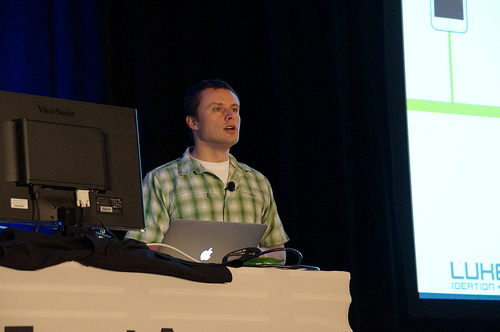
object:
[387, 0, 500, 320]
computer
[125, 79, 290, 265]
guy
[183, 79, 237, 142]
hair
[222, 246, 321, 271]
cables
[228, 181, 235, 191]
microphone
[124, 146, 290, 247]
shirt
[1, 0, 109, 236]
drapes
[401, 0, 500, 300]
display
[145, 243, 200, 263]
cords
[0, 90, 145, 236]
computer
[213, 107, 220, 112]
eye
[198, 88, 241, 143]
face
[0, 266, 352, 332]
desk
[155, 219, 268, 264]
computer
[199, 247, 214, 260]
apple logo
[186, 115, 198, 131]
ear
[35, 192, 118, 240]
cord